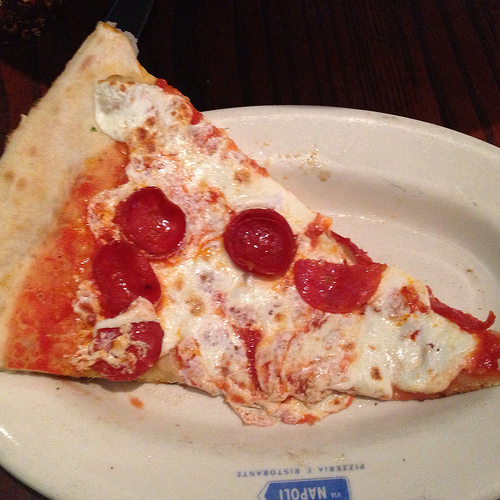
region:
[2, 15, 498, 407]
slice of pizza on plate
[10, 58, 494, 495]
a white plate on table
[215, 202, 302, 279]
pepperoni on a pizza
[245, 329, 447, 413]
melting cheese on pizza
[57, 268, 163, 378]
red sauce on pizza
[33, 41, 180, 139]
crust of a pizza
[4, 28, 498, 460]
pizza on a white plate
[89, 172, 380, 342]
pepperonis on a pizza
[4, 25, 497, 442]
a big slice of pizza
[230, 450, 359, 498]
markings on the plate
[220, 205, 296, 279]
pepperoni on the slice of pizza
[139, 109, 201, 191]
melted cheese on the pizza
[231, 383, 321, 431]
melted cheese sliding off the pizza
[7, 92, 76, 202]
crust of the pizza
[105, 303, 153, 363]
cheese on top of the pepperoni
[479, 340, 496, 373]
tomato sauce on the pizza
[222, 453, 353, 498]
blue label on the plate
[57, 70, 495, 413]
slice of pizza on the plate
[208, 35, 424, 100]
brown wood table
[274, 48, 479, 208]
white plate on the table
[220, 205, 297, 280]
One of five pepperonis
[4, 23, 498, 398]
Pepperoni and chese pizza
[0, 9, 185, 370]
Crust of pizza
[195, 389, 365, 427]
Melted cheese falling on plate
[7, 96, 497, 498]
White plate under pizza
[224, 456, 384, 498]
Brand name of the white plate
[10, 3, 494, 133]
Dark wooden table in the background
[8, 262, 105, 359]
Part of pizza where cheese has fallen off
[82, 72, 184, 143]
Melted cheese on pizza crust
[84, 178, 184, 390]
Three pieces of pepperoni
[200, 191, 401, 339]
pepperoni on a pizza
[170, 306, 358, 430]
melting cheese on a pizza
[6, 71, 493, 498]
plate with a pizza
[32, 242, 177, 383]
red sauce of a pizza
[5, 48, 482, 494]
large slice of pizza on plate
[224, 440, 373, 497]
markings on a plate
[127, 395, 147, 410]
sauce on a plate